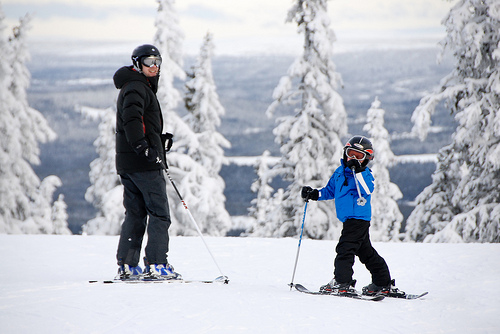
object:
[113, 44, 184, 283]
man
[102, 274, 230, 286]
skis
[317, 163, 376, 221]
parka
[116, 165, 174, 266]
pants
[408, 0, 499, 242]
tree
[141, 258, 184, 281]
boots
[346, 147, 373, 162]
googles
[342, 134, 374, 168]
helmet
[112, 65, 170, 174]
jacket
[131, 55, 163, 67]
goggles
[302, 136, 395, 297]
boy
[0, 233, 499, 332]
ground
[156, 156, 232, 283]
pole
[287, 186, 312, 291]
ski pole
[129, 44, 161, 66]
hat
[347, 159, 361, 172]
hand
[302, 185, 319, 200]
glove